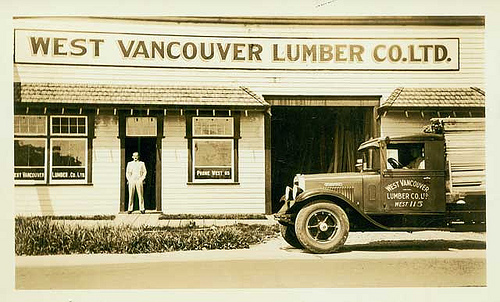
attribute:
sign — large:
[10, 29, 464, 77]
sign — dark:
[182, 162, 242, 184]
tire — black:
[295, 200, 350, 251]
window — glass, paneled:
[21, 80, 131, 230]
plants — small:
[15, 223, 231, 251]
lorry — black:
[279, 114, 487, 253]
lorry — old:
[208, 72, 471, 261]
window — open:
[388, 144, 425, 173]